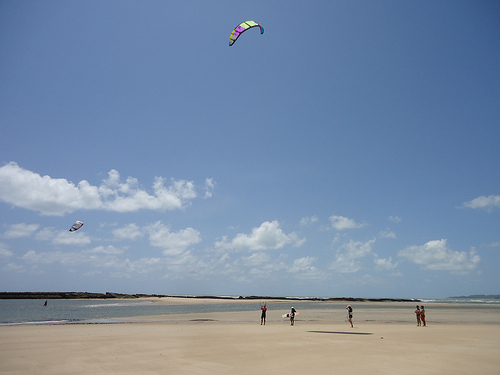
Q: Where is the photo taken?
A: Beach.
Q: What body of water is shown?
A: Ocean.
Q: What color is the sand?
A: Tan.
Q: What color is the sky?
A: Blue.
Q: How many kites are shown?
A: 2.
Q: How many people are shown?
A: 6.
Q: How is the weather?
A: Sunny.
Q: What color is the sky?
A: Blue.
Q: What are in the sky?
A: Kites.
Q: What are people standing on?
A: Sand.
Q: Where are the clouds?
A: Low in the sky.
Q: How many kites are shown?
A: Two.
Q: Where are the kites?
A: In the sky.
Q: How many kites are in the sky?
A: Two.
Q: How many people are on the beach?
A: Five.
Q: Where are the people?
A: On the beach.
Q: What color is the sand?
A: Tan.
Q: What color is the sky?
A: Blue.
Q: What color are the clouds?
A: White.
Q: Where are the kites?
A: In the sky.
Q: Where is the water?
A: To the left of the people.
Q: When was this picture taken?
A: This picture was taken in the day time.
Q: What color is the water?
A: The water is blue.